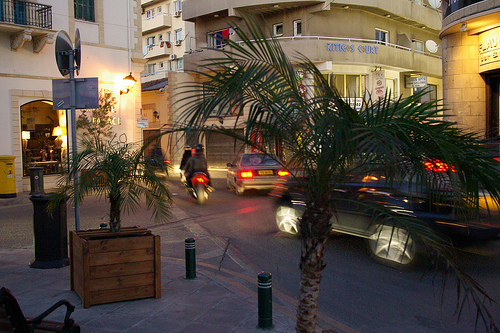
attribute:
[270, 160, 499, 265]
car — black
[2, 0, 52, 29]
railing — black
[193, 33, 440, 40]
railing — black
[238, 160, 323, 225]
trunk — grey, brown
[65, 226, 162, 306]
box — wooden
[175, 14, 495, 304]
tree — palm, smaller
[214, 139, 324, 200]
car — brown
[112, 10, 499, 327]
leaves — long, green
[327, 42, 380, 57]
writing — blue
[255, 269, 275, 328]
pole — green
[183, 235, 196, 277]
pole — green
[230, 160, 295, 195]
grey car — small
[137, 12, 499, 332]
tree — small, palm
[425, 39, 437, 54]
dish — satellite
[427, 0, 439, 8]
dish — satellite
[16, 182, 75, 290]
garbage can — outdoor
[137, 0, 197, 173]
building — yellow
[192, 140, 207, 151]
helmet — blue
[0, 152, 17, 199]
trash can — yellow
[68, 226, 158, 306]
crate — large, wooden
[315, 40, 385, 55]
lettering — blue